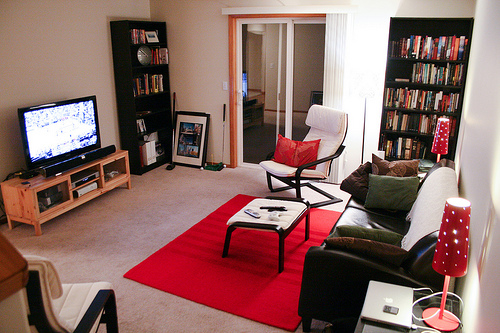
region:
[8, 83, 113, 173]
A tv.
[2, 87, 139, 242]
The tv is on a stand.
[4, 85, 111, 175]
The tv is on.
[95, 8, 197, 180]
A black bookshelf.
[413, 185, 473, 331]
A desk lamp.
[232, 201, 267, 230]
A remote on the table.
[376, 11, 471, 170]
The bookshelf is fell.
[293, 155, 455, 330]
A couch.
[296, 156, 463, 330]
The couch has a lot of pillows on it.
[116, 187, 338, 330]
A red rug on the floor.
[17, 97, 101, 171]
television that is turned on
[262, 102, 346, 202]
black and white chair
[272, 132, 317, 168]
red pillow on a chair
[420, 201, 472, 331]
red and white lamp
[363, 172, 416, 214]
green pillow on a couch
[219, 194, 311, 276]
coffee table on a red rug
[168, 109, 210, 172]
picture in a frame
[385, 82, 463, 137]
books on a bookshelf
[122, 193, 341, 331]
a red rug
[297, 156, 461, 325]
a couch between two lamps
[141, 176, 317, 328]
the rug on the floor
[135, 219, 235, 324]
the rug is red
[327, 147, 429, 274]
pillows on the couch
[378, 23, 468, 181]
books in the shelf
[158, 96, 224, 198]
picture leaning on the wall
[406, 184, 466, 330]
the lamp is red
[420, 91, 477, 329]
lamps on the side tables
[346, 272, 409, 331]
the laptop is silver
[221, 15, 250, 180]
door frame is brown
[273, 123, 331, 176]
the pillow is red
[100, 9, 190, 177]
The bookshelf is black.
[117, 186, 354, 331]
A red rug is on the floor.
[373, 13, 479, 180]
The shelf is full of books.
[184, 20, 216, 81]
The walls are off white.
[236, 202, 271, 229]
A remote is on the table.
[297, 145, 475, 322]
A lot of pillows are on the couch.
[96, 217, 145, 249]
The carpet is off white.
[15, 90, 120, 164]
Flat screen TV is on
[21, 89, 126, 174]
Flat screen TV is big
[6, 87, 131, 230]
Flat screen TV sitting on stand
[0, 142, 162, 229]
TV stand has openings in frong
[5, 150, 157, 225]
TV stand is made of wood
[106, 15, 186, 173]
Bookcase has a lot of books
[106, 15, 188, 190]
Bookcase is made of dark wood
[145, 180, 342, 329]
Table sitting on rug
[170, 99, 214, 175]
Picture sitting on the floor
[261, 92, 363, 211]
White chair has a red pillow